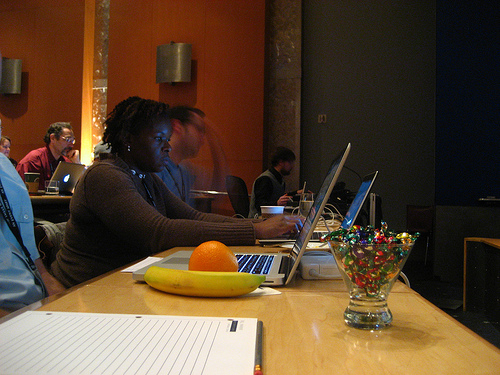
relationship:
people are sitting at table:
[2, 95, 314, 314] [2, 216, 499, 373]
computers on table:
[130, 140, 354, 289] [2, 216, 499, 373]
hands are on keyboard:
[252, 213, 308, 239] [282, 231, 339, 241]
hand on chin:
[63, 148, 80, 162] [63, 148, 72, 158]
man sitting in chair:
[249, 145, 314, 220] [222, 173, 250, 220]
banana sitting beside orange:
[142, 265, 267, 300] [190, 237, 240, 276]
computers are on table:
[130, 140, 381, 289] [2, 216, 499, 373]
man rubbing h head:
[157, 100, 230, 215] [188, 109, 204, 127]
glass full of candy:
[318, 222, 421, 334] [320, 226, 421, 294]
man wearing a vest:
[249, 145, 314, 220] [250, 170, 287, 220]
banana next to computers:
[142, 265, 267, 300] [130, 140, 354, 289]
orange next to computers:
[190, 237, 240, 276] [130, 140, 354, 289]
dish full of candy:
[318, 222, 421, 334] [320, 226, 421, 294]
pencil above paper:
[251, 319, 268, 375] [0, 309, 263, 374]